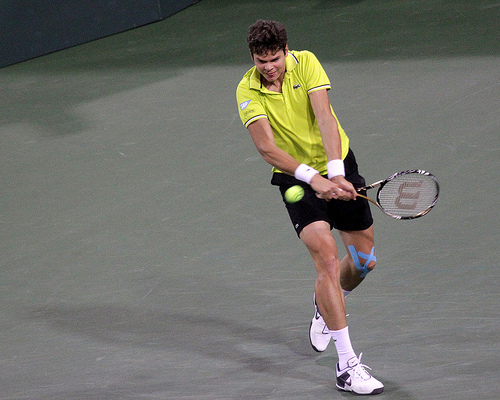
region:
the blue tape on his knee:
[349, 243, 376, 282]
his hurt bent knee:
[346, 241, 379, 288]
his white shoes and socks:
[326, 324, 372, 395]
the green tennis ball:
[278, 178, 304, 206]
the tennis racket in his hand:
[357, 171, 445, 213]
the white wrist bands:
[296, 161, 346, 180]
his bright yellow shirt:
[246, 62, 342, 169]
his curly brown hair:
[247, 21, 287, 52]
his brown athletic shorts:
[273, 169, 375, 228]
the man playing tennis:
[233, 26, 390, 391]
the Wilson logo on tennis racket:
[381, 173, 433, 217]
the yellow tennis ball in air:
[282, 183, 307, 205]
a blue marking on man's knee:
[345, 243, 382, 273]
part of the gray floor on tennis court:
[22, 74, 234, 369]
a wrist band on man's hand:
[322, 158, 347, 173]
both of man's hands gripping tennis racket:
[308, 173, 358, 200]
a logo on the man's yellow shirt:
[291, 83, 307, 91]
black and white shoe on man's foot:
[330, 362, 385, 391]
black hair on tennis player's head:
[254, 25, 284, 51]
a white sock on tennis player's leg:
[332, 331, 357, 363]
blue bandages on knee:
[345, 244, 381, 280]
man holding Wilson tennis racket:
[318, 164, 446, 226]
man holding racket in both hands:
[296, 167, 443, 219]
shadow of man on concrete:
[23, 283, 404, 394]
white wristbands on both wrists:
[281, 157, 354, 185]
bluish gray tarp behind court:
[0, 0, 206, 75]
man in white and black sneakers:
[299, 282, 392, 396]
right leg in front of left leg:
[296, 282, 391, 392]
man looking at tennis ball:
[243, 20, 355, 208]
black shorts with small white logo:
[266, 161, 376, 236]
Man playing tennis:
[235, 17, 385, 395]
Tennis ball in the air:
[283, 184, 304, 203]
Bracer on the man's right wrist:
[293, 164, 319, 184]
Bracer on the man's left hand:
[325, 158, 345, 178]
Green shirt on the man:
[237, 51, 349, 191]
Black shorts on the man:
[271, 149, 374, 239]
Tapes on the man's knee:
[347, 243, 377, 280]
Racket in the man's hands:
[317, 169, 441, 218]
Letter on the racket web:
[393, 179, 423, 211]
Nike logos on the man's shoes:
[313, 309, 353, 386]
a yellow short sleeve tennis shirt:
[236, 52, 350, 175]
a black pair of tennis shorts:
[269, 160, 376, 235]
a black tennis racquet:
[350, 168, 440, 219]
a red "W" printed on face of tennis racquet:
[394, 178, 426, 213]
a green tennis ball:
[283, 184, 304, 202]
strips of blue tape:
[348, 243, 378, 285]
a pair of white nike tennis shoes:
[309, 295, 386, 395]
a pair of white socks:
[329, 286, 357, 373]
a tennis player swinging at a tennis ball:
[235, 18, 442, 395]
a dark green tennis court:
[0, 0, 497, 395]